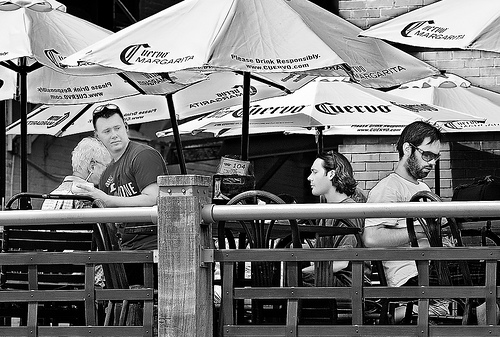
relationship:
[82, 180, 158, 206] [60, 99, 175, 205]
arm are walking on person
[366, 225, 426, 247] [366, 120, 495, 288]
arm of person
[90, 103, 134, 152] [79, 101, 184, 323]
head of a person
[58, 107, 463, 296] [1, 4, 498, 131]
people under umbrellas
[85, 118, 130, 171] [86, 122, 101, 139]
earbuds in h ears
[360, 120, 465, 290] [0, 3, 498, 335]
man sitting in a cafe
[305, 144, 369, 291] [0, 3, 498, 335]
person sitting in a cafe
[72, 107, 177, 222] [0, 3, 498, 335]
person sitting in a cafe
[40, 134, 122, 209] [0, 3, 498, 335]
person sitting in a cafe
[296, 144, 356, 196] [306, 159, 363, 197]
head of a person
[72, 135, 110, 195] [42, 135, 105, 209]
head of person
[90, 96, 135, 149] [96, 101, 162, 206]
head of person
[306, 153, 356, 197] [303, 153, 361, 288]
head of person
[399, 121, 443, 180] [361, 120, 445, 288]
head of person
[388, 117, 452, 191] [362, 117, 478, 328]
head of person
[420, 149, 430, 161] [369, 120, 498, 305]
eye of person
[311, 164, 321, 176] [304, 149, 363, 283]
eye of person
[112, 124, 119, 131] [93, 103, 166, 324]
eye of person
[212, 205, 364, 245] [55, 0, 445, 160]
table under umbrella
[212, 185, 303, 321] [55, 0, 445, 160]
chair under umbrella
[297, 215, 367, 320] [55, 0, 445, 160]
chair under umbrella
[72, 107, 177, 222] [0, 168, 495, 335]
person on patio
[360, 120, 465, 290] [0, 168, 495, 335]
man on patio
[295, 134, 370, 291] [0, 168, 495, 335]
person on patio